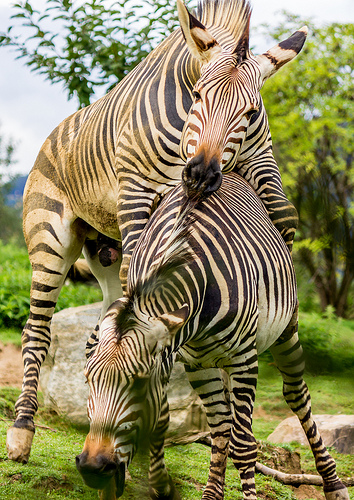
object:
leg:
[225, 335, 259, 499]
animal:
[6, 0, 309, 499]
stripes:
[156, 34, 190, 143]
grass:
[0, 358, 353, 500]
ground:
[0, 242, 353, 499]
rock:
[41, 299, 212, 442]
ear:
[257, 23, 308, 88]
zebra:
[73, 158, 352, 499]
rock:
[264, 411, 353, 457]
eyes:
[189, 89, 202, 104]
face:
[181, 45, 261, 195]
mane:
[111, 203, 198, 344]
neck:
[135, 248, 208, 383]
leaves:
[304, 312, 322, 336]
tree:
[259, 21, 353, 319]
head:
[72, 298, 190, 499]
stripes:
[187, 221, 231, 343]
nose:
[74, 445, 117, 474]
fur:
[167, 268, 195, 304]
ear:
[143, 303, 189, 344]